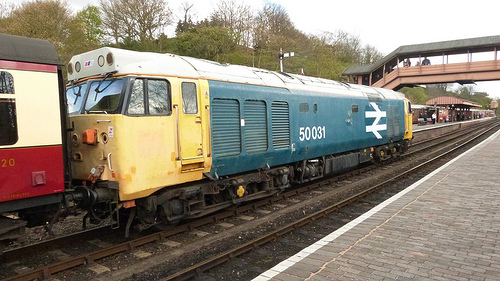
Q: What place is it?
A: It is a railroad.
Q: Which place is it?
A: It is a railroad.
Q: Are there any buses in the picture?
A: No, there are no buses.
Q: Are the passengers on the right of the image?
A: Yes, the passengers are on the right of the image.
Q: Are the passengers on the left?
A: No, the passengers are on the right of the image.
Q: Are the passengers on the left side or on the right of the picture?
A: The passengers are on the right of the image.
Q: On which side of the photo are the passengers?
A: The passengers are on the right of the image.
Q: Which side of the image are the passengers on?
A: The passengers are on the right of the image.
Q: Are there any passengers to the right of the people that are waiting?
A: Yes, there are passengers to the right of the people.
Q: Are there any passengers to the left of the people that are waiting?
A: No, the passengers are to the right of the people.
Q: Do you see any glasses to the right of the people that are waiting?
A: No, there are passengers to the right of the people.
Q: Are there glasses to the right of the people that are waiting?
A: No, there are passengers to the right of the people.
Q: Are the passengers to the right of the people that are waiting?
A: Yes, the passengers are to the right of the people.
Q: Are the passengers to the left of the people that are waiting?
A: No, the passengers are to the right of the people.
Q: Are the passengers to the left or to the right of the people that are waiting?
A: The passengers are to the right of the people.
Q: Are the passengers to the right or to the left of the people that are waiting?
A: The passengers are to the right of the people.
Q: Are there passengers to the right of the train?
A: Yes, there are passengers to the right of the train.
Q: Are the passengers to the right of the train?
A: Yes, the passengers are to the right of the train.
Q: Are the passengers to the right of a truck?
A: No, the passengers are to the right of the train.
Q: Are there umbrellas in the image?
A: No, there are no umbrellas.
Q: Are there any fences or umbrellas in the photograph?
A: No, there are no umbrellas or fences.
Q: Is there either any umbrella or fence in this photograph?
A: No, there are no umbrellas or fences.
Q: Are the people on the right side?
A: Yes, the people are on the right of the image.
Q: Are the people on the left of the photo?
A: No, the people are on the right of the image.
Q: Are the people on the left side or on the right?
A: The people are on the right of the image.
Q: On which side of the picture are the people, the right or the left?
A: The people are on the right of the image.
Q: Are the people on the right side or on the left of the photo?
A: The people are on the right of the image.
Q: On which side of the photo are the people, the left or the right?
A: The people are on the right of the image.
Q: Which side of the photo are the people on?
A: The people are on the right of the image.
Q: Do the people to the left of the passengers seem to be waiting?
A: Yes, the people are waiting.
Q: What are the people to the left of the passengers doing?
A: The people are waiting.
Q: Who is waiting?
A: The people are waiting.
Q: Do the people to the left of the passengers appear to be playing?
A: No, the people are waiting.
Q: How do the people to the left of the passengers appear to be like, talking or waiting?
A: The people are waiting.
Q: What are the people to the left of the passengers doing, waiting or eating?
A: The people are waiting.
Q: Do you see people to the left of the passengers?
A: Yes, there are people to the left of the passengers.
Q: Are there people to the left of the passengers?
A: Yes, there are people to the left of the passengers.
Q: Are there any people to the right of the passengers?
A: No, the people are to the left of the passengers.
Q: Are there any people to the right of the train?
A: Yes, there are people to the right of the train.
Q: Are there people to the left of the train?
A: No, the people are to the right of the train.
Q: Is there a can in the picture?
A: No, there are no cans.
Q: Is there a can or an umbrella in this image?
A: No, there are no cans or umbrellas.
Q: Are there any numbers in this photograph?
A: Yes, there are numbers.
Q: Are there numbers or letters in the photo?
A: Yes, there are numbers.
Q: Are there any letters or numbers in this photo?
A: Yes, there are numbers.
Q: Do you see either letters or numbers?
A: Yes, there are numbers.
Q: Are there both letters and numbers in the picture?
A: No, there are numbers but no letters.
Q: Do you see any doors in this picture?
A: Yes, there is a door.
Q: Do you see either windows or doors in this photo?
A: Yes, there is a door.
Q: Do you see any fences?
A: No, there are no fences.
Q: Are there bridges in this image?
A: Yes, there is a bridge.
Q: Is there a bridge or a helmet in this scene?
A: Yes, there is a bridge.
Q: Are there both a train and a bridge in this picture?
A: Yes, there are both a bridge and a train.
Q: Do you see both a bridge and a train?
A: Yes, there are both a bridge and a train.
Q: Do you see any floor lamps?
A: No, there are no floor lamps.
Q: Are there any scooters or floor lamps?
A: No, there are no floor lamps or scooters.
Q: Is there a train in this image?
A: Yes, there is a train.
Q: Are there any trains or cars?
A: Yes, there is a train.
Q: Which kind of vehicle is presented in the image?
A: The vehicle is a train.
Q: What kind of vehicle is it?
A: The vehicle is a train.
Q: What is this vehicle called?
A: This is a train.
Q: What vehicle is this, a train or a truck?
A: This is a train.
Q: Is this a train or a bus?
A: This is a train.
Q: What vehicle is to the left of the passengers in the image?
A: The vehicle is a train.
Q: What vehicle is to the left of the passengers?
A: The vehicle is a train.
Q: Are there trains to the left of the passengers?
A: Yes, there is a train to the left of the passengers.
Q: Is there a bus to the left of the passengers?
A: No, there is a train to the left of the passengers.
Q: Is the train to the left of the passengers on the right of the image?
A: Yes, the train is to the left of the passengers.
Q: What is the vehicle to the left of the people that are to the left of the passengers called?
A: The vehicle is a train.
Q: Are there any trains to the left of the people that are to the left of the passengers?
A: Yes, there is a train to the left of the people.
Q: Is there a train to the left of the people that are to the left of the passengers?
A: Yes, there is a train to the left of the people.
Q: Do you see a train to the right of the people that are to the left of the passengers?
A: No, the train is to the left of the people.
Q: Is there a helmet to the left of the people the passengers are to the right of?
A: No, there is a train to the left of the people.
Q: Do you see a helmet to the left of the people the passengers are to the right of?
A: No, there is a train to the left of the people.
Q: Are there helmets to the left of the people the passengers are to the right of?
A: No, there is a train to the left of the people.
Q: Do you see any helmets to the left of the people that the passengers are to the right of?
A: No, there is a train to the left of the people.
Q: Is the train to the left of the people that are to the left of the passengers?
A: Yes, the train is to the left of the people.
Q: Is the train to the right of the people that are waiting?
A: No, the train is to the left of the people.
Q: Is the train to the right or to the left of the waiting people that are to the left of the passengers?
A: The train is to the left of the people.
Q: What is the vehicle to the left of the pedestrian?
A: The vehicle is a train.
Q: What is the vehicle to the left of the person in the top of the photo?
A: The vehicle is a train.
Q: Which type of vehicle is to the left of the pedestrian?
A: The vehicle is a train.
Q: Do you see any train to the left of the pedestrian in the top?
A: Yes, there is a train to the left of the pedestrian.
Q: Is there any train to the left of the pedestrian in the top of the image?
A: Yes, there is a train to the left of the pedestrian.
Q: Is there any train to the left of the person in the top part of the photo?
A: Yes, there is a train to the left of the pedestrian.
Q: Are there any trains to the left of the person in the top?
A: Yes, there is a train to the left of the pedestrian.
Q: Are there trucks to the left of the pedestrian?
A: No, there is a train to the left of the pedestrian.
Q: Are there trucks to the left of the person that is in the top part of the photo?
A: No, there is a train to the left of the pedestrian.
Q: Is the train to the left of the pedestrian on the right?
A: Yes, the train is to the left of the pedestrian.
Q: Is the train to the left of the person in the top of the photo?
A: Yes, the train is to the left of the pedestrian.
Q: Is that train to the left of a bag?
A: No, the train is to the left of the pedestrian.